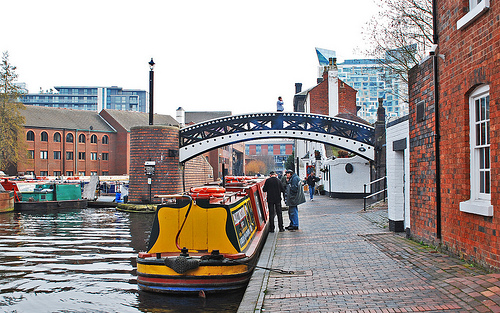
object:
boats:
[137, 178, 270, 293]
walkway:
[238, 186, 500, 312]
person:
[264, 170, 286, 232]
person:
[284, 169, 307, 230]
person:
[307, 172, 322, 202]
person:
[277, 96, 284, 115]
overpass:
[179, 112, 374, 161]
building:
[410, 1, 500, 270]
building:
[17, 104, 133, 176]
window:
[459, 80, 494, 216]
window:
[40, 131, 50, 143]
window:
[53, 131, 62, 143]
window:
[67, 133, 75, 143]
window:
[78, 132, 87, 143]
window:
[89, 134, 99, 144]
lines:
[271, 238, 368, 247]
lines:
[265, 284, 442, 300]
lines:
[338, 302, 464, 311]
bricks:
[419, 161, 428, 170]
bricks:
[408, 138, 422, 147]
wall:
[409, 55, 441, 246]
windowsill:
[459, 197, 493, 218]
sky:
[2, 2, 434, 114]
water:
[0, 208, 247, 312]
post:
[149, 71, 155, 126]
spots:
[284, 130, 305, 135]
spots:
[185, 145, 197, 151]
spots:
[221, 133, 240, 141]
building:
[314, 45, 418, 117]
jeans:
[289, 205, 300, 228]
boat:
[18, 182, 87, 212]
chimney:
[328, 57, 339, 118]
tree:
[0, 48, 30, 170]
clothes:
[262, 177, 285, 229]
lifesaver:
[189, 185, 226, 193]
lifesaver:
[224, 176, 246, 180]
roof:
[20, 105, 181, 133]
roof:
[186, 111, 229, 124]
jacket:
[287, 173, 306, 206]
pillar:
[130, 126, 184, 203]